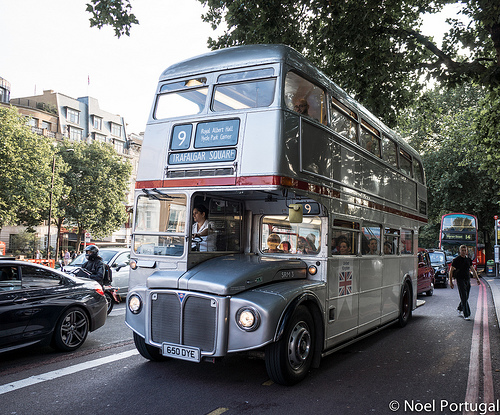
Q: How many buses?
A: 1.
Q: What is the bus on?
A: The street.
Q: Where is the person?
A: Behind the bus.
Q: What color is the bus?
A: Gray.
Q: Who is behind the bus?
A: The man.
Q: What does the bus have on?
A: Headlights.